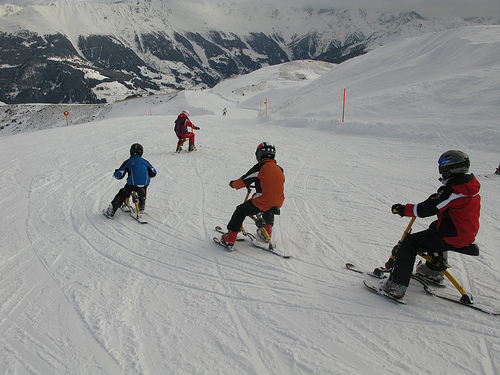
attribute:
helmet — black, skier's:
[130, 145, 145, 156]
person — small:
[211, 142, 289, 257]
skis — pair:
[343, 255, 495, 320]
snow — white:
[52, 264, 281, 341]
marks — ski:
[93, 254, 339, 328]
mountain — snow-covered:
[8, 6, 349, 102]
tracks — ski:
[95, 229, 204, 274]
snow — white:
[13, 222, 209, 369]